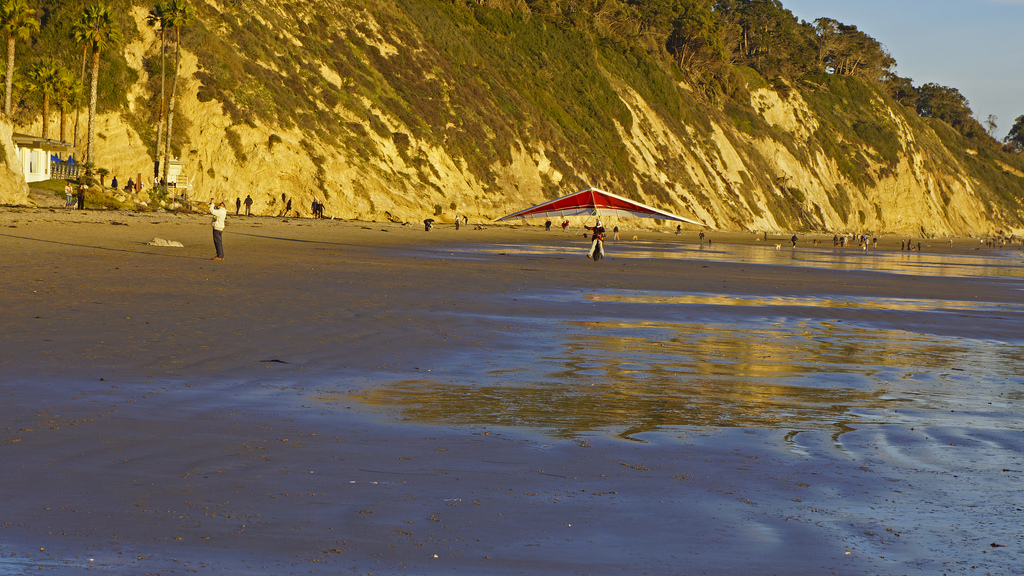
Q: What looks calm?
A: The water.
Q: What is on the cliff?
A: Greenery.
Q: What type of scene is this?
A: A daytime scene.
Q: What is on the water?
A: Reflections.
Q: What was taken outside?
A: The photo.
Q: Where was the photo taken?
A: At the beach.